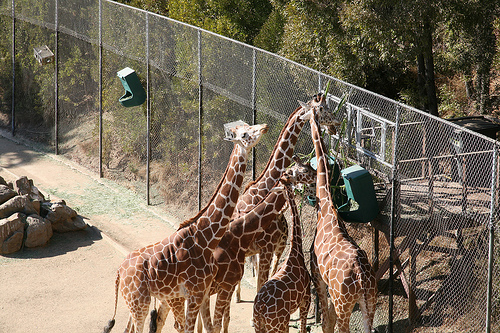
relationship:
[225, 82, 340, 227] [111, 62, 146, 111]
giraffe in bin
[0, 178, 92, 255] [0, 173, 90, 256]
rock in a pile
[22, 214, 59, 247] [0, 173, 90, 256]
rock in a pile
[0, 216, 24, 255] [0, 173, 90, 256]
rock in a pile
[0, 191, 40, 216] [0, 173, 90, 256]
rock in a pile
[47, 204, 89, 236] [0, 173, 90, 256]
rock in a pile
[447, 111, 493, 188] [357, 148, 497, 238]
can on a platform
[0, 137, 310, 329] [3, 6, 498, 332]
floor in a enclosure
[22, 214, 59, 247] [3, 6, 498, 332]
rock in a enclosure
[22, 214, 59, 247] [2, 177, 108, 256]
rock in a pile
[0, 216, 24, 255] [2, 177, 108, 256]
rock in a pile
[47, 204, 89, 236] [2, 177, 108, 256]
rock in a pile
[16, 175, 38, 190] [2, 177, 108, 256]
rock in a pile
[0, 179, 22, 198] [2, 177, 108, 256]
rock in a pile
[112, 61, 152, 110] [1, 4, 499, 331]
feeder on a fence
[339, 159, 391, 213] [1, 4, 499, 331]
feeder on a fence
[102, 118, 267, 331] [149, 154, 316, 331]
giraffe with a giraffe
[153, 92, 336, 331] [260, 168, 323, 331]
giraffe with a giraffe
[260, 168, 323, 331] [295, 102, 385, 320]
giraffe with a giraffe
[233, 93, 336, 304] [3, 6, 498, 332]
giraffe in a enclosure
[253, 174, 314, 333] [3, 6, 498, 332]
giraffe in a enclosure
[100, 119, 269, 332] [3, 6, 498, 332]
giraffe in a enclosure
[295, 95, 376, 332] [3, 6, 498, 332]
giraffe in a enclosure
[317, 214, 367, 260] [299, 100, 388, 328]
back of a giraffe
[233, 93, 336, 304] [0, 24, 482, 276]
giraffe contained in a fence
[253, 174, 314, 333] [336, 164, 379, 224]
giraffe standing at bins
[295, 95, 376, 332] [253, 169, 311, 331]
giraffe standing behind other giraffe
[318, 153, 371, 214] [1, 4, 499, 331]
bins attached to fence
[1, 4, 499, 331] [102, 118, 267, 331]
fence securing giraffe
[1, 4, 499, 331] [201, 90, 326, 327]
fence securing giraffe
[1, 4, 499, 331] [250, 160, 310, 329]
fence securing giraffe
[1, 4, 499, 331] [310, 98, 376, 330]
fence securing giraffe